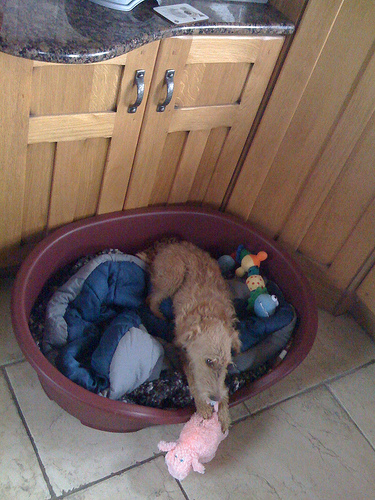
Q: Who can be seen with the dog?
A: No one.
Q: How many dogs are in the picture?
A: One.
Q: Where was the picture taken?
A: A house.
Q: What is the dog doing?
A: Playing with a toy.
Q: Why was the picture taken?
A: To capture the dog.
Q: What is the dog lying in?
A: A dog bed.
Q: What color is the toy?
A: Pink.